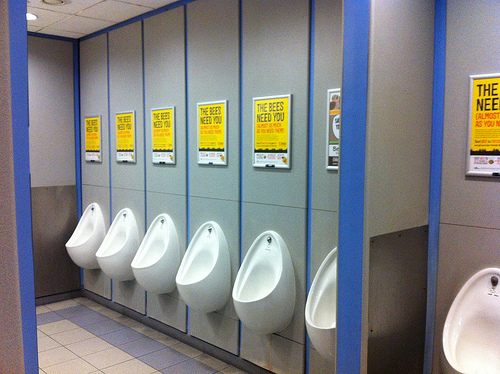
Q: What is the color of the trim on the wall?
A: Blue.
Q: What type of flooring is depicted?
A: Tile.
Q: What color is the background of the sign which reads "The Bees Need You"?
A: Yellow.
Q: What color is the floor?
A: Blue and grey.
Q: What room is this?
A: Restroom.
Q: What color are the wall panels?
A: Grey.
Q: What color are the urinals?
A: White.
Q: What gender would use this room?
A: Males.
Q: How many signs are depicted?
A: 7.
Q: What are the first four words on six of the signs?
A: The bees need you.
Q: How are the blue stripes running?
A: Vertically.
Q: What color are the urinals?
A: White.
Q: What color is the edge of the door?
A: Blue.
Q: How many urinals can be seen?
A: 7.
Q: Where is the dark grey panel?
A: By the last urinal.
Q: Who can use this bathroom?
A: Males.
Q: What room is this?
A: Bathroom.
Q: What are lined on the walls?
A: Urinals.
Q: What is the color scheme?
A: Blue and gray.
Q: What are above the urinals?
A: Signs.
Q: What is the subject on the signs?
A: Bees.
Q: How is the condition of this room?
A: Clean.